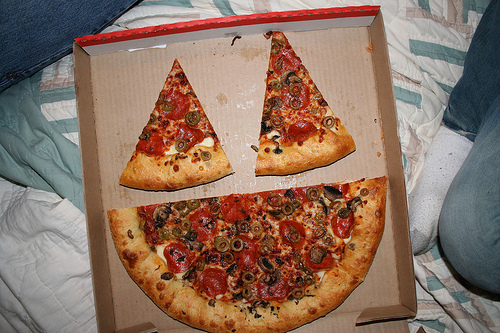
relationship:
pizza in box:
[117, 56, 237, 193] [71, 6, 415, 331]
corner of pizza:
[359, 174, 389, 206] [105, 174, 389, 333]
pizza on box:
[256, 31, 351, 183] [71, 6, 415, 331]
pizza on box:
[119, 62, 222, 182] [71, 6, 415, 331]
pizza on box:
[105, 174, 389, 333] [71, 6, 415, 331]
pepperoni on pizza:
[217, 196, 252, 224] [118, 59, 243, 186]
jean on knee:
[438, 131, 499, 273] [435, 188, 499, 295]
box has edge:
[71, 6, 415, 331] [72, 2, 384, 52]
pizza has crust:
[100, 37, 404, 324] [105, 127, 386, 331]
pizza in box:
[105, 174, 389, 333] [71, 6, 415, 331]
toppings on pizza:
[162, 210, 219, 242] [119, 205, 365, 305]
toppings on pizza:
[256, 215, 341, 260] [119, 205, 365, 305]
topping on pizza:
[280, 221, 308, 252] [100, 37, 404, 324]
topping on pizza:
[229, 233, 248, 252] [111, 192, 388, 331]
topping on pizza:
[213, 234, 230, 256] [111, 192, 388, 331]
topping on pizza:
[234, 217, 253, 234] [111, 192, 388, 331]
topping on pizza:
[179, 218, 193, 233] [111, 192, 388, 331]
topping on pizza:
[241, 267, 257, 284] [111, 192, 388, 331]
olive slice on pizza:
[234, 239, 243, 251] [105, 174, 389, 333]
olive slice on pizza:
[215, 239, 228, 249] [105, 174, 389, 333]